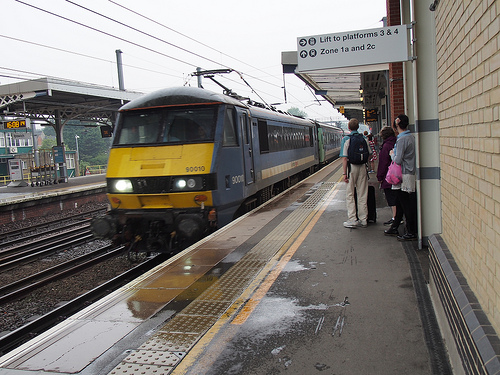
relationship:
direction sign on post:
[296, 23, 410, 70] [403, 4, 438, 242]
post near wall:
[403, 4, 438, 242] [385, 4, 497, 374]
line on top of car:
[70, 20, 107, 38] [90, 87, 350, 263]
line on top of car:
[126, 23, 150, 40] [90, 87, 350, 263]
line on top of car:
[171, 31, 201, 47] [90, 87, 350, 263]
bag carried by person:
[385, 160, 403, 185] [393, 115, 416, 245]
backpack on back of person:
[344, 133, 369, 165] [337, 115, 365, 229]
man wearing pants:
[329, 109, 376, 227] [343, 163, 374, 228]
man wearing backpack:
[339, 119, 373, 228] [351, 138, 369, 168]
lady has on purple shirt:
[374, 124, 398, 241] [379, 142, 394, 176]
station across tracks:
[0, 120, 91, 187] [0, 186, 120, 346]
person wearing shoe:
[384, 114, 418, 241] [394, 222, 426, 243]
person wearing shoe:
[384, 114, 418, 241] [380, 224, 401, 236]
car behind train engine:
[90, 87, 367, 242] [84, 80, 305, 220]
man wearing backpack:
[339, 119, 373, 228] [345, 133, 374, 172]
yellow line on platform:
[0, 153, 355, 373] [0, 154, 449, 374]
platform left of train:
[0, 171, 110, 210] [82, 86, 342, 251]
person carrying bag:
[384, 114, 418, 241] [386, 159, 403, 184]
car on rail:
[90, 87, 350, 263] [0, 204, 164, 352]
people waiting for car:
[337, 114, 427, 246] [90, 87, 350, 263]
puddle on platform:
[12, 237, 350, 373] [0, 154, 449, 374]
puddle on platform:
[251, 180, 347, 215] [0, 154, 449, 374]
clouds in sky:
[0, 0, 386, 124] [210, 22, 291, 67]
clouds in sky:
[199, 0, 290, 41] [2, 4, 294, 49]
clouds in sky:
[0, 0, 386, 124] [2, 0, 391, 122]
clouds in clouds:
[0, 0, 386, 124] [0, 0, 386, 124]